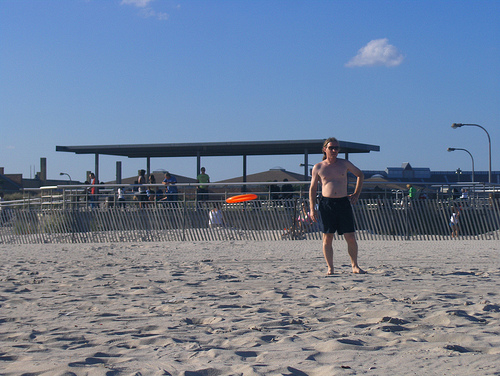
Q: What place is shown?
A: It is a beach.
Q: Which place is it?
A: It is a beach.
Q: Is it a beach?
A: Yes, it is a beach.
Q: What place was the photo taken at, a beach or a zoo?
A: It was taken at a beach.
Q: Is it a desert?
A: No, it is a beach.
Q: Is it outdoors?
A: Yes, it is outdoors.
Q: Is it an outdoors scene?
A: Yes, it is outdoors.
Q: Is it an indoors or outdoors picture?
A: It is outdoors.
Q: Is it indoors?
A: No, it is outdoors.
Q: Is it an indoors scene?
A: No, it is outdoors.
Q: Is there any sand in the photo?
A: Yes, there is sand.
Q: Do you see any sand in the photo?
A: Yes, there is sand.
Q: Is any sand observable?
A: Yes, there is sand.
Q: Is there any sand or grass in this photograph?
A: Yes, there is sand.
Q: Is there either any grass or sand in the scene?
A: Yes, there is sand.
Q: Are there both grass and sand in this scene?
A: No, there is sand but no grass.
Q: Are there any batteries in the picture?
A: No, there are no batteries.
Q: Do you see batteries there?
A: No, there are no batteries.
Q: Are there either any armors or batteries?
A: No, there are no batteries or armors.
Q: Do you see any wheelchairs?
A: No, there are no wheelchairs.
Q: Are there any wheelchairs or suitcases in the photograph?
A: No, there are no wheelchairs or suitcases.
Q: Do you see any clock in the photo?
A: No, there are no clocks.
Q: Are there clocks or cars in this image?
A: No, there are no clocks or cars.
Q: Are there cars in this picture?
A: No, there are no cars.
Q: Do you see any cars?
A: No, there are no cars.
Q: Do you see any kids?
A: No, there are no kids.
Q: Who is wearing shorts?
A: The man is wearing shorts.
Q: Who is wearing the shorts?
A: The man is wearing shorts.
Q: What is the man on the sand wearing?
A: The man is wearing shorts.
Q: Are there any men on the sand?
A: Yes, there is a man on the sand.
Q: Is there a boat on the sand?
A: No, there is a man on the sand.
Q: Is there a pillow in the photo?
A: No, there are no pillows.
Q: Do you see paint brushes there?
A: No, there are no paint brushes.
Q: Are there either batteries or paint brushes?
A: No, there are no paint brushes or batteries.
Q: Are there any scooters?
A: No, there are no scooters.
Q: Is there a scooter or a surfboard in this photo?
A: No, there are no scooters or surfboards.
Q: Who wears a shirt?
A: The man wears a shirt.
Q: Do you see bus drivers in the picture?
A: No, there are no bus drivers.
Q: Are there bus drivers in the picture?
A: No, there are no bus drivers.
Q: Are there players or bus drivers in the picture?
A: No, there are no bus drivers or players.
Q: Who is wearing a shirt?
A: The man is wearing a shirt.